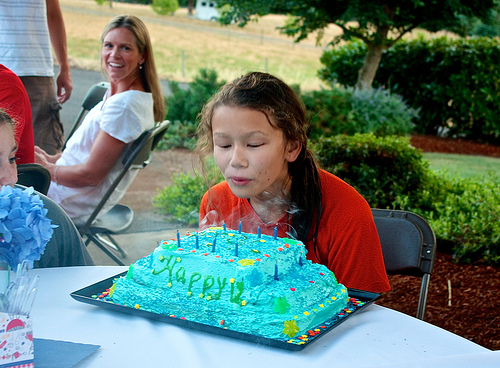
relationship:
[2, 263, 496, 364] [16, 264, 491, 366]
surface of table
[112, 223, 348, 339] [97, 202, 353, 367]
icing of cake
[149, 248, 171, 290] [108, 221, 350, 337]
green letter on birthday cake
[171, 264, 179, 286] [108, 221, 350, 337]
green letter on birthday cake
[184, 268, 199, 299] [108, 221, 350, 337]
green letter on birthday cake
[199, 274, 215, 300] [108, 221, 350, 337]
green letter on birthday cake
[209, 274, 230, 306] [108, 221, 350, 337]
green letter on birthday cake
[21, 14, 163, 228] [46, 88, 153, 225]
girl wearing shirt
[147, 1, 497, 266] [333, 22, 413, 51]
leaves on branches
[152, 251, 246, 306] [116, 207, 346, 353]
writing on cake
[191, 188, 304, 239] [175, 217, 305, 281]
smoke from candles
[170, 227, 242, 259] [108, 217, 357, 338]
candles on birthday cake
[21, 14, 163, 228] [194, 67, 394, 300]
girl watching girl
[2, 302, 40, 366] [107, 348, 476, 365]
present on table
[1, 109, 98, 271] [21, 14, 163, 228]
girl looking at girl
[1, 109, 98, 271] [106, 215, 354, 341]
girl looking at cake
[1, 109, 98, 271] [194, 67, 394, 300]
girl looking at girl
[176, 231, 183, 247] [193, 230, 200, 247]
candle on candle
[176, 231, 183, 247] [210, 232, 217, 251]
candle on candle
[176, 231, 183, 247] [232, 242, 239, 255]
candle on candle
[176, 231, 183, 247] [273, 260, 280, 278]
candle on candle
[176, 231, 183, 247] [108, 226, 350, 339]
candle on cake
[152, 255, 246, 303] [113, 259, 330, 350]
word happy written on cake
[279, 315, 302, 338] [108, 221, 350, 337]
yellow flower on birthday cake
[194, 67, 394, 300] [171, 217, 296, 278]
girl blowing out candles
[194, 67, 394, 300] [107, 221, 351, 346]
girl blowing out birthday cake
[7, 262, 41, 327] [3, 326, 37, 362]
utensils in a box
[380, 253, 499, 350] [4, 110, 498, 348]
mulch on ground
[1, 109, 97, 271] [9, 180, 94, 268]
girl in green shirt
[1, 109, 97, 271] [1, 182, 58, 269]
girl behind blue flowers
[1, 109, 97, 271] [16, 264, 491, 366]
girl sitting at table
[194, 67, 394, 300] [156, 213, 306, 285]
girl blowing out candles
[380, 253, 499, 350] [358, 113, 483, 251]
mulch of garden